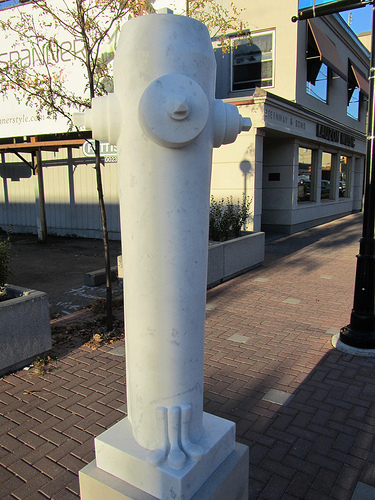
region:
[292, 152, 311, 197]
window on side of building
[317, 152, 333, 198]
window on side of building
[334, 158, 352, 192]
window on side of building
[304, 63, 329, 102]
window on side of building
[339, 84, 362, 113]
window on side of building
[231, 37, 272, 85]
window on side of building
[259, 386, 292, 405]
brick on the sidewalk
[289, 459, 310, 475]
brick on the sidewalk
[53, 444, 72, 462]
brick on the sidewalk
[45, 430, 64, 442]
brick on the sidewalk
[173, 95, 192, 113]
a white diamond shape on the front of a pole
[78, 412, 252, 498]
the square base of a pole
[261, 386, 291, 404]
a gray concrete square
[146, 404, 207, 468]
three boot shaped designs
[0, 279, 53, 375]
the corner of a concrete planter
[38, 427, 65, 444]
a red concrete tile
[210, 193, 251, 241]
green plants growing in a planter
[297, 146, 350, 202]
three windows along the front of a building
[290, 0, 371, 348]
a tall metal pole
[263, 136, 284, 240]
the dark doorway to a building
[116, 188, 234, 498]
A white concret pillar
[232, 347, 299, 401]
A brown tile floor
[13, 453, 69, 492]
A brown tile floor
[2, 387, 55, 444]
A brown tile floor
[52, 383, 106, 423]
A brown tile floor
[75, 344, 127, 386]
A brown tile floor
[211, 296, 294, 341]
A brown tile floor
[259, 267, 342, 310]
A brown tile floor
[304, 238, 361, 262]
A brown tile floor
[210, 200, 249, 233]
small green tree branches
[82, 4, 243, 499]
The fire hydrant is white.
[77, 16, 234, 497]
The fire hydrant is huge.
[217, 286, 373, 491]
The sidewalk is brick.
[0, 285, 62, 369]
The planter is concrete.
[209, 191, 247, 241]
The plants are leafy.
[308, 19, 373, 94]
The awnings are out.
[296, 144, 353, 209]
The windows are in the building.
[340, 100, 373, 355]
The pole is black.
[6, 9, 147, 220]
The building is white.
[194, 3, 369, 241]
The building is tan.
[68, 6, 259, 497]
Statue of fire hydrant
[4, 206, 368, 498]
A brick walk way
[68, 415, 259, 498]
The base of a statue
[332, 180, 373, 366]
The base of light pole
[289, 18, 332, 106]
Windows on a building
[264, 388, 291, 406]
A grey brick in walk way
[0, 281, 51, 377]
A concrete plant housing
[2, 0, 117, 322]
A small dying tree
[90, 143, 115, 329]
A small tree trunk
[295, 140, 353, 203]
Windows of a building